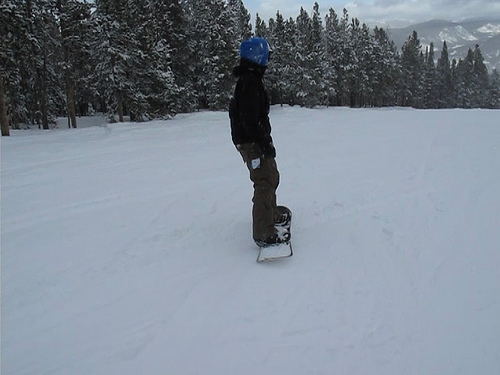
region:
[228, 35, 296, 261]
person in blue helmet is snowboarding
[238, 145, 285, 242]
person wearing brown snow pants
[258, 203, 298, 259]
snowboard on snow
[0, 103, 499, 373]
white snow under snowboard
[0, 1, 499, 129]
forest behind person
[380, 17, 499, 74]
mountains behind forest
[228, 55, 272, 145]
person wearing black jacket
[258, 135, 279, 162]
person wearing black gloves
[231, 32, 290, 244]
person is standing upright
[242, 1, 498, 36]
gray sky above mountains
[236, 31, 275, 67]
a blue helmet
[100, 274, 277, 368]
white snow with snowboard tracks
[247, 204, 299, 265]
a snow covered snowboard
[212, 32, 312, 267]
a snowboarder looking away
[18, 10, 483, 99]
a forest of evergreen trees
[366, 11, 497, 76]
snow peppered mountains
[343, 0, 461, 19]
a sky heavy with grey clouds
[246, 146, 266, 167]
blue and white gloves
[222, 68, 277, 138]
a black hoodie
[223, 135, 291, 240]
brown khaki pants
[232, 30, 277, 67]
a blue hat on a snow boarder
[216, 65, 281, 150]
a black coat on a snowboarder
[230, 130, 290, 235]
grey pants on a snowboarder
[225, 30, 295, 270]
a snowboarder on a snowboard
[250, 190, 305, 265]
a snowboard headed down a slope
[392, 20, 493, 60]
a mountain in the distance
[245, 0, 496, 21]
a cloudy blue sky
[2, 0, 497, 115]
a forest of pines along a slope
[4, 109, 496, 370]
a snowy white slope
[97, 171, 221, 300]
tracks in the snow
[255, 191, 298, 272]
The snowboard the guy is standing on.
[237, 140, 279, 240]
The pants the snowboarder is wearing.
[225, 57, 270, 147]
The black jacket the guy is wearing.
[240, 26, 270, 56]
The blue helmet the guy is wearing.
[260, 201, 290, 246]
The black shoes the guy is wearing.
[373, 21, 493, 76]
The snow covered mountains in the background.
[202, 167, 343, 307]
The area where the man is standing on the snowboard.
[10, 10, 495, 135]
The snow covered trees in the background.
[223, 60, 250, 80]
The hood of the black jacket the snowboarder is wearing.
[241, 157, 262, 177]
The white paper or tag hanging out of the snowboarder's back pant pocket.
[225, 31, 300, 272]
person snowboarding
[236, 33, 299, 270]
person snowboarding on snowy mountain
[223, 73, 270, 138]
snowboarder wearing black jacket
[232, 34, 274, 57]
snowboarder wearing blue helmet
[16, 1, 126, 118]
trees with snow covered green leaves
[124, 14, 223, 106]
trees with snow covered green leaves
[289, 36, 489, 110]
trees with snow covered green leaves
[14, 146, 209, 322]
white snow on mountain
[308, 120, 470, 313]
white snow on mountain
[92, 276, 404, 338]
white snow on mountain